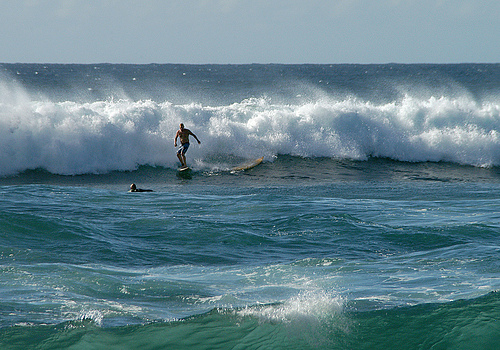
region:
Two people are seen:
[111, 120, 201, 205]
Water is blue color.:
[65, 200, 140, 260]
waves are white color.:
[20, 106, 96, 142]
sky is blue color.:
[17, 16, 394, 42]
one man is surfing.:
[166, 120, 205, 182]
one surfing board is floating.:
[213, 148, 276, 181]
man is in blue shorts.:
[175, 138, 197, 158]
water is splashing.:
[3, 76, 30, 118]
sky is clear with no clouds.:
[25, 18, 457, 60]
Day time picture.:
[15, 16, 487, 338]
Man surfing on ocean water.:
[167, 120, 204, 175]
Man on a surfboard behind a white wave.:
[164, 119, 208, 191]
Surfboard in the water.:
[232, 156, 268, 176]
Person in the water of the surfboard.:
[120, 178, 162, 200]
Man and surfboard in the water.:
[123, 156, 268, 201]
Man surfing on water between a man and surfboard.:
[159, 115, 204, 180]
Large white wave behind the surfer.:
[3, 91, 498, 187]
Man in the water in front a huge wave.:
[125, 125, 170, 197]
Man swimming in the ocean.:
[118, 180, 165, 210]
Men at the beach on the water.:
[119, 119, 205, 205]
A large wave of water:
[16, 73, 495, 168]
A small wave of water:
[200, 282, 389, 344]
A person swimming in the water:
[121, 178, 156, 203]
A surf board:
[215, 155, 281, 182]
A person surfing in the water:
[161, 123, 205, 194]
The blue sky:
[1, 1, 497, 63]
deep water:
[17, 179, 497, 338]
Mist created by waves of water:
[3, 59, 489, 122]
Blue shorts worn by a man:
[166, 136, 198, 160]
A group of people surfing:
[76, 20, 494, 345]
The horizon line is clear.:
[6, 34, 498, 93]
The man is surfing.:
[155, 115, 202, 176]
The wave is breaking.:
[22, 83, 490, 155]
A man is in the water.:
[123, 177, 148, 196]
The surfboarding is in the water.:
[221, 150, 294, 183]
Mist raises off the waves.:
[26, 67, 470, 117]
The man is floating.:
[114, 173, 178, 234]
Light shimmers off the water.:
[7, 53, 212, 114]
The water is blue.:
[28, 80, 465, 329]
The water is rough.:
[60, 81, 420, 331]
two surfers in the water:
[88, 98, 255, 251]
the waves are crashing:
[258, 80, 389, 198]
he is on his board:
[148, 110, 208, 200]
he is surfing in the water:
[157, 115, 202, 193]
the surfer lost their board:
[102, 168, 290, 213]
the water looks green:
[355, 298, 406, 340]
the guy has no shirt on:
[156, 113, 231, 260]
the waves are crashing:
[298, 82, 394, 152]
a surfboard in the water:
[224, 142, 280, 200]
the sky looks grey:
[289, 22, 372, 60]